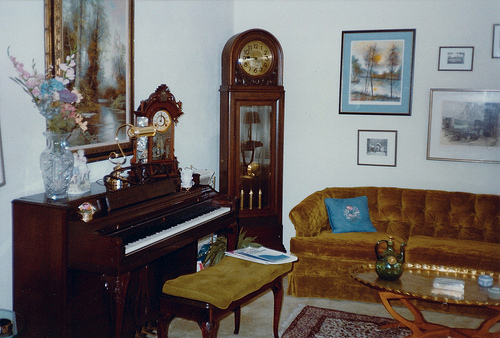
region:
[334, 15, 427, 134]
painting on the wall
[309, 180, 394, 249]
the pillow is blue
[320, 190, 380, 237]
Blue pillow sitting on a brown couch.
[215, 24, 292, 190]
Grandfather clock sitting in the corner of the room.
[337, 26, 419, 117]
Picture of trees with a black frame.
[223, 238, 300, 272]
Stack of papers sitting on a bench.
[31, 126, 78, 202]
Vase sitting on top of a piano.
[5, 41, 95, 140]
Light colored flowers in a vase.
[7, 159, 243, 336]
Brown piano.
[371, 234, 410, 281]
Glass teapot on a table.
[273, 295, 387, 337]
Red and white colored rug.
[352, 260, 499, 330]
Brown coffee table.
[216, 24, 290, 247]
a grandfather clock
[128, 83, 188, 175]
a clock on a piano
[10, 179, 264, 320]
a small piano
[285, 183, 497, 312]
a dark yellow couch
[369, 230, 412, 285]
an ornate tea pot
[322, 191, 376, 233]
a blue pillow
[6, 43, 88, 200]
flowers in a pot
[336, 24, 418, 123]
a painting on a wall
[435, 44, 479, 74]
a photograph on the wall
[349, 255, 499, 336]
a coffee table with a wooden bottom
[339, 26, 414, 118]
picture hanging on the wall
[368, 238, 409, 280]
figurine on the table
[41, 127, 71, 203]
vase on the piano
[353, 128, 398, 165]
picture on the wall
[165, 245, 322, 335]
bench next to the piano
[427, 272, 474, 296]
paper on table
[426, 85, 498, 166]
picture handing on the wall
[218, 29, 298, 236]
clock in the corner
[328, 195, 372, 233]
pillow on the couch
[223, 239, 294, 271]
paper on the bench